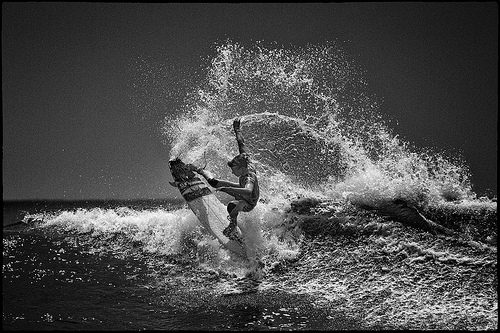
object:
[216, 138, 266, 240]
man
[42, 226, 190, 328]
water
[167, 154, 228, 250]
board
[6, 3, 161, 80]
sky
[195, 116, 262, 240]
surfer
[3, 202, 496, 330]
ocean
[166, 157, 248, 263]
surfboard